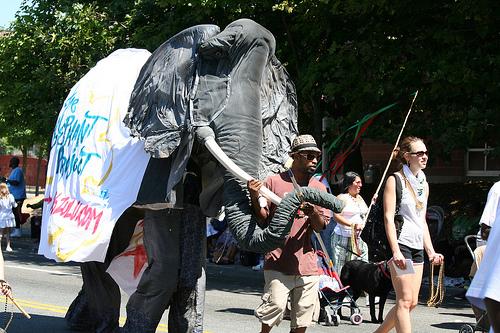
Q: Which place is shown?
A: It is a street.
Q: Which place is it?
A: It is a street.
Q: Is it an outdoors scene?
A: Yes, it is outdoors.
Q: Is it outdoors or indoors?
A: It is outdoors.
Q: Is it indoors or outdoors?
A: It is outdoors.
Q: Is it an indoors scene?
A: No, it is outdoors.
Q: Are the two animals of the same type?
A: No, they are dogs and elephants.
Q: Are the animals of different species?
A: Yes, they are dogs and elephants.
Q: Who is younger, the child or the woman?
A: The child is younger than the woman.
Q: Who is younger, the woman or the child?
A: The child is younger than the woman.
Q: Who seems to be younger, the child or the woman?
A: The child is younger than the woman.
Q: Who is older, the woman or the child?
A: The woman is older than the child.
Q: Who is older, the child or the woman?
A: The woman is older than the child.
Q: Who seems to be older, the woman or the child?
A: The woman is older than the child.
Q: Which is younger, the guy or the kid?
A: The kid is younger than the guy.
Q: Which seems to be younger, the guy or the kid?
A: The kid is younger than the guy.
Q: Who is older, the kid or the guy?
A: The guy is older than the kid.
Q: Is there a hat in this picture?
A: Yes, there is a hat.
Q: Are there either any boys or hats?
A: Yes, there is a hat.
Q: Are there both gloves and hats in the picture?
A: No, there is a hat but no gloves.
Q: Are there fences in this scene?
A: No, there are no fences.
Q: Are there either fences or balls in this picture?
A: No, there are no fences or balls.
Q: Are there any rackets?
A: No, there are no rackets.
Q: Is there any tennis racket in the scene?
A: No, there are no rackets.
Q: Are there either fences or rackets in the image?
A: No, there are no rackets or fences.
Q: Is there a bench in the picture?
A: No, there are no benches.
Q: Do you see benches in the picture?
A: No, there are no benches.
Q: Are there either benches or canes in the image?
A: No, there are no benches or canes.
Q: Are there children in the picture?
A: Yes, there is a child.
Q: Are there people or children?
A: Yes, there is a child.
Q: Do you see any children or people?
A: Yes, there is a child.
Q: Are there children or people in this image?
A: Yes, there is a child.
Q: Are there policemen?
A: No, there are no policemen.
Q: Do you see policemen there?
A: No, there are no policemen.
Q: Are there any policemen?
A: No, there are no policemen.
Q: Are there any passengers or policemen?
A: No, there are no policemen or passengers.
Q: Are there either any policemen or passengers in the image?
A: No, there are no policemen or passengers.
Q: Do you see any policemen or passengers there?
A: No, there are no policemen or passengers.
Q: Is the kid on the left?
A: Yes, the kid is on the left of the image.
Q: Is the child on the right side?
A: No, the child is on the left of the image.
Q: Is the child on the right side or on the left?
A: The child is on the left of the image.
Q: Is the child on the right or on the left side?
A: The child is on the left of the image.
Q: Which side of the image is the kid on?
A: The kid is on the left of the image.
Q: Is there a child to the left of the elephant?
A: Yes, there is a child to the left of the elephant.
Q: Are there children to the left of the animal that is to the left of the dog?
A: Yes, there is a child to the left of the elephant.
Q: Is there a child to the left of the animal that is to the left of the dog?
A: Yes, there is a child to the left of the elephant.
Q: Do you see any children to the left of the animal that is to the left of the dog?
A: Yes, there is a child to the left of the elephant.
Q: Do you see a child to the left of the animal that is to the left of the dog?
A: Yes, there is a child to the left of the elephant.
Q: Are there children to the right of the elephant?
A: No, the child is to the left of the elephant.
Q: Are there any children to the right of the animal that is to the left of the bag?
A: No, the child is to the left of the elephant.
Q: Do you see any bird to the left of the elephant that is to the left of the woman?
A: No, there is a child to the left of the elephant.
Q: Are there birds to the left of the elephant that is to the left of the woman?
A: No, there is a child to the left of the elephant.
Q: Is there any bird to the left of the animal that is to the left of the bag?
A: No, there is a child to the left of the elephant.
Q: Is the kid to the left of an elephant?
A: Yes, the kid is to the left of an elephant.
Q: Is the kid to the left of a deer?
A: No, the kid is to the left of an elephant.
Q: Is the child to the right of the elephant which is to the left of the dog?
A: No, the child is to the left of the elephant.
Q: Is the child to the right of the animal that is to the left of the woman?
A: No, the child is to the left of the elephant.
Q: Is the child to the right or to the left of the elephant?
A: The child is to the left of the elephant.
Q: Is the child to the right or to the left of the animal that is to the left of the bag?
A: The child is to the left of the elephant.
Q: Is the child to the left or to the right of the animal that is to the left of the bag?
A: The child is to the left of the elephant.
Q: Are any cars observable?
A: No, there are no cars.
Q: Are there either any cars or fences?
A: No, there are no cars or fences.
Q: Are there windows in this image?
A: Yes, there is a window.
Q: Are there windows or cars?
A: Yes, there is a window.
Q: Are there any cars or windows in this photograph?
A: Yes, there is a window.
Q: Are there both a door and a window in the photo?
A: No, there is a window but no doors.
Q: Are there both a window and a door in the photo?
A: No, there is a window but no doors.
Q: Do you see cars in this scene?
A: No, there are no cars.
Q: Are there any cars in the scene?
A: No, there are no cars.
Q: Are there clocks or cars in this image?
A: No, there are no cars or clocks.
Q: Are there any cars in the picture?
A: No, there are no cars.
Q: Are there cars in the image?
A: No, there are no cars.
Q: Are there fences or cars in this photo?
A: No, there are no cars or fences.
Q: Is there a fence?
A: No, there are no fences.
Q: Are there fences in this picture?
A: No, there are no fences.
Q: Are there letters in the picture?
A: Yes, there are letters.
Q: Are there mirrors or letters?
A: Yes, there are letters.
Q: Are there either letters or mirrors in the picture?
A: Yes, there are letters.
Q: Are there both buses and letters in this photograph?
A: No, there are letters but no buses.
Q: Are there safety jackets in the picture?
A: No, there are no safety jackets.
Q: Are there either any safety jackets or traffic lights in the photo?
A: No, there are no safety jackets or traffic lights.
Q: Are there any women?
A: Yes, there is a woman.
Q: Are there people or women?
A: Yes, there is a woman.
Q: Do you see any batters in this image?
A: No, there are no batters.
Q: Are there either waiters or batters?
A: No, there are no batters or waiters.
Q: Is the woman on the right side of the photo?
A: Yes, the woman is on the right of the image.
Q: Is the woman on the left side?
A: No, the woman is on the right of the image.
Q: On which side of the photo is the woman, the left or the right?
A: The woman is on the right of the image.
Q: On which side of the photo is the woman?
A: The woman is on the right of the image.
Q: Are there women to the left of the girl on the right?
A: Yes, there is a woman to the left of the girl.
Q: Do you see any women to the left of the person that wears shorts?
A: Yes, there is a woman to the left of the girl.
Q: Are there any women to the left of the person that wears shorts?
A: Yes, there is a woman to the left of the girl.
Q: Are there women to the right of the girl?
A: No, the woman is to the left of the girl.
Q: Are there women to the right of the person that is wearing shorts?
A: No, the woman is to the left of the girl.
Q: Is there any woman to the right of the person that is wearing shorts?
A: No, the woman is to the left of the girl.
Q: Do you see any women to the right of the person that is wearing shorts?
A: No, the woman is to the left of the girl.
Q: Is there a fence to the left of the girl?
A: No, there is a woman to the left of the girl.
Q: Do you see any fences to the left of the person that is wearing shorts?
A: No, there is a woman to the left of the girl.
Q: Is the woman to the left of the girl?
A: Yes, the woman is to the left of the girl.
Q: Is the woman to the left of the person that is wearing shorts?
A: Yes, the woman is to the left of the girl.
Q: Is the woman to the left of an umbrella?
A: No, the woman is to the left of the girl.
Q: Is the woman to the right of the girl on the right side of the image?
A: No, the woman is to the left of the girl.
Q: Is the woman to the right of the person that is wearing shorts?
A: No, the woman is to the left of the girl.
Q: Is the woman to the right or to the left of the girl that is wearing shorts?
A: The woman is to the left of the girl.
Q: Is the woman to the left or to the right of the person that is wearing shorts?
A: The woman is to the left of the girl.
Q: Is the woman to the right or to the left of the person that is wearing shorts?
A: The woman is to the left of the girl.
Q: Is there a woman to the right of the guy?
A: Yes, there is a woman to the right of the guy.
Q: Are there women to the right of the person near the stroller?
A: Yes, there is a woman to the right of the guy.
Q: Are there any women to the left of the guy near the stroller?
A: No, the woman is to the right of the guy.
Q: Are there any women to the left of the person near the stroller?
A: No, the woman is to the right of the guy.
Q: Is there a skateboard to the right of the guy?
A: No, there is a woman to the right of the guy.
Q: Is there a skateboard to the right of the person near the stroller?
A: No, there is a woman to the right of the guy.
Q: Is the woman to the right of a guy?
A: Yes, the woman is to the right of a guy.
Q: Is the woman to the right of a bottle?
A: No, the woman is to the right of a guy.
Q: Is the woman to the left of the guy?
A: No, the woman is to the right of the guy.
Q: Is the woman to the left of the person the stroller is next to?
A: No, the woman is to the right of the guy.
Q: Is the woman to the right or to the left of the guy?
A: The woman is to the right of the guy.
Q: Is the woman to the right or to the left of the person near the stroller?
A: The woman is to the right of the guy.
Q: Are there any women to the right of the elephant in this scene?
A: Yes, there is a woman to the right of the elephant.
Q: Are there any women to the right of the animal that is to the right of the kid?
A: Yes, there is a woman to the right of the elephant.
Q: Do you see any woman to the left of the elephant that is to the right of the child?
A: No, the woman is to the right of the elephant.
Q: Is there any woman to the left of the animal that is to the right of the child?
A: No, the woman is to the right of the elephant.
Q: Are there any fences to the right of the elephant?
A: No, there is a woman to the right of the elephant.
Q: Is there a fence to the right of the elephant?
A: No, there is a woman to the right of the elephant.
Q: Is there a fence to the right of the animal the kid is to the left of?
A: No, there is a woman to the right of the elephant.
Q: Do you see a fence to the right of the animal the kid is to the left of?
A: No, there is a woman to the right of the elephant.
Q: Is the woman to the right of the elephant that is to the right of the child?
A: Yes, the woman is to the right of the elephant.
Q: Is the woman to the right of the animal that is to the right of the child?
A: Yes, the woman is to the right of the elephant.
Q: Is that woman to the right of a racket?
A: No, the woman is to the right of the elephant.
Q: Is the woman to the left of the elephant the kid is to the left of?
A: No, the woman is to the right of the elephant.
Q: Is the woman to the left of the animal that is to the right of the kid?
A: No, the woman is to the right of the elephant.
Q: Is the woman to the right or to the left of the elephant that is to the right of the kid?
A: The woman is to the right of the elephant.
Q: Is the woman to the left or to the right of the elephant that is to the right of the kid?
A: The woman is to the right of the elephant.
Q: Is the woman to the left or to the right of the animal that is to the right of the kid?
A: The woman is to the right of the elephant.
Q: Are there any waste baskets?
A: No, there are no waste baskets.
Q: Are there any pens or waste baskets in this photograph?
A: No, there are no waste baskets or pens.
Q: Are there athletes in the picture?
A: No, there are no athletes.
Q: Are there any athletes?
A: No, there are no athletes.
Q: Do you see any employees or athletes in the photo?
A: No, there are no athletes or employees.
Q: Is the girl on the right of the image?
A: Yes, the girl is on the right of the image.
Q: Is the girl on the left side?
A: No, the girl is on the right of the image.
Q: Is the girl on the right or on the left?
A: The girl is on the right of the image.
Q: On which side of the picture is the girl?
A: The girl is on the right of the image.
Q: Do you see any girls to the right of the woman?
A: Yes, there is a girl to the right of the woman.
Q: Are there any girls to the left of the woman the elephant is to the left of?
A: No, the girl is to the right of the woman.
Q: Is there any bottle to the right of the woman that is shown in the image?
A: No, there is a girl to the right of the woman.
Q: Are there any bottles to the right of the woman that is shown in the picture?
A: No, there is a girl to the right of the woman.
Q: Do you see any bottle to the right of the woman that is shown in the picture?
A: No, there is a girl to the right of the woman.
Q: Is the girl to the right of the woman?
A: Yes, the girl is to the right of the woman.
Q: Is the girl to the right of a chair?
A: No, the girl is to the right of the woman.